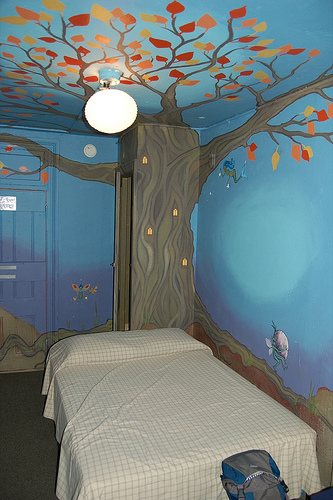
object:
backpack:
[220, 449, 291, 500]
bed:
[39, 326, 322, 500]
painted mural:
[0, 0, 332, 488]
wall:
[192, 76, 332, 488]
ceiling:
[0, 0, 333, 137]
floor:
[0, 370, 58, 500]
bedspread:
[41, 325, 322, 500]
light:
[84, 88, 139, 134]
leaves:
[165, 0, 184, 21]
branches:
[2, 162, 46, 180]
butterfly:
[72, 284, 90, 301]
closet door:
[117, 175, 133, 331]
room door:
[0, 189, 48, 372]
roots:
[192, 288, 332, 432]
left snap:
[281, 481, 290, 494]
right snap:
[238, 488, 246, 498]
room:
[0, 1, 333, 500]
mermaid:
[218, 158, 249, 187]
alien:
[265, 319, 288, 373]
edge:
[86, 433, 315, 500]